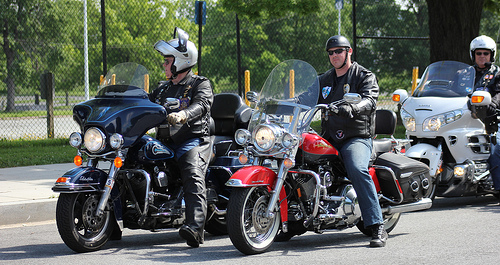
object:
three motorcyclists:
[141, 28, 498, 250]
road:
[1, 166, 500, 262]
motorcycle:
[214, 60, 436, 257]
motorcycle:
[380, 59, 499, 211]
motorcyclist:
[281, 35, 390, 249]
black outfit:
[312, 65, 380, 145]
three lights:
[68, 126, 125, 152]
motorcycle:
[47, 55, 273, 256]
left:
[1, 35, 62, 193]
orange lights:
[70, 156, 85, 166]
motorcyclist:
[112, 33, 213, 252]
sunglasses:
[327, 48, 345, 55]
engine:
[298, 164, 341, 209]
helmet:
[149, 28, 203, 74]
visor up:
[171, 26, 190, 50]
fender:
[224, 165, 297, 222]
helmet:
[322, 34, 354, 47]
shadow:
[0, 242, 87, 262]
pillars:
[258, 60, 319, 125]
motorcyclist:
[447, 35, 500, 212]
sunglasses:
[475, 51, 490, 56]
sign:
[190, 1, 212, 26]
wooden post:
[43, 69, 56, 140]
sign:
[35, 72, 57, 100]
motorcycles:
[227, 58, 437, 252]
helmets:
[323, 35, 352, 48]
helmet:
[467, 33, 495, 61]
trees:
[4, 0, 86, 93]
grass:
[4, 137, 67, 161]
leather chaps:
[172, 137, 214, 224]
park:
[2, 2, 500, 111]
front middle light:
[250, 123, 279, 153]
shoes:
[363, 224, 388, 247]